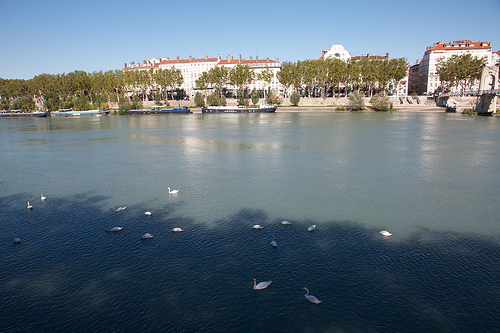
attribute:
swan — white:
[104, 220, 128, 240]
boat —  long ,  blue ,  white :
[1, 106, 48, 118]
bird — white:
[250, 221, 267, 232]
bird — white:
[100, 224, 124, 234]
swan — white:
[248, 272, 276, 294]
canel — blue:
[367, 202, 413, 281]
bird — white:
[301, 284, 321, 304]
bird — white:
[140, 230, 152, 240]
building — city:
[405, 35, 498, 111]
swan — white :
[142, 230, 154, 240]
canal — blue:
[1, 115, 498, 330]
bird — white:
[378, 224, 399, 243]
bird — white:
[162, 185, 179, 195]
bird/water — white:
[294, 277, 330, 312]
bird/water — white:
[247, 272, 279, 293]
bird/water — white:
[157, 176, 192, 199]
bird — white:
[37, 191, 49, 202]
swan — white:
[167, 219, 184, 241]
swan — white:
[251, 275, 271, 293]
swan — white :
[299, 285, 321, 305]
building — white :
[417, 39, 494, 94]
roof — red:
[426, 37, 492, 52]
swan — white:
[157, 179, 178, 202]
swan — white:
[245, 272, 282, 297]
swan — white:
[295, 281, 333, 311]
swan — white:
[370, 222, 397, 243]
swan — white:
[135, 222, 160, 244]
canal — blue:
[145, 129, 409, 191]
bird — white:
[170, 223, 183, 235]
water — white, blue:
[9, 112, 499, 331]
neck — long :
[166, 187, 174, 197]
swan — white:
[380, 227, 399, 240]